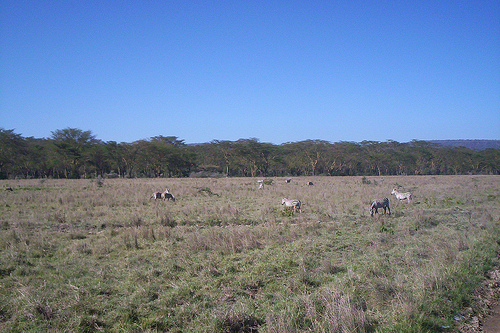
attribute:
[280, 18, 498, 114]
clouds — white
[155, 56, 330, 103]
sky — blue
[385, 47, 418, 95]
clouds — white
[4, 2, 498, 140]
sky — blue